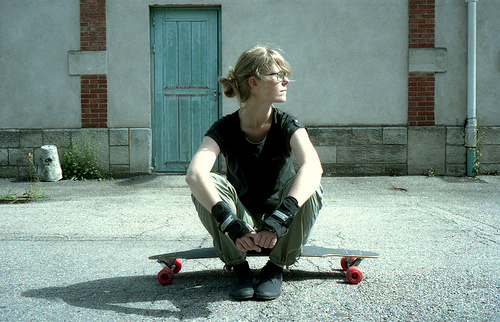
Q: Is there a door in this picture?
A: Yes, there is a door.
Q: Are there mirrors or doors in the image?
A: Yes, there is a door.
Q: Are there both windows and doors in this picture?
A: No, there is a door but no windows.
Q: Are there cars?
A: No, there are no cars.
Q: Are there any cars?
A: No, there are no cars.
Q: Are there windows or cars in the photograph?
A: No, there are no cars or windows.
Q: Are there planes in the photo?
A: No, there are no planes.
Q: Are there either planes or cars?
A: No, there are no planes or cars.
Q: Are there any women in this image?
A: Yes, there is a woman.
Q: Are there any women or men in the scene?
A: Yes, there is a woman.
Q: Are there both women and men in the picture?
A: No, there is a woman but no men.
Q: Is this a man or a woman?
A: This is a woman.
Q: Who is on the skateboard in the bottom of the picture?
A: The woman is on the skateboard.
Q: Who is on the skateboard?
A: The woman is on the skateboard.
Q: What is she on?
A: The woman is on the skateboard.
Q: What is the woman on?
A: The woman is on the skateboard.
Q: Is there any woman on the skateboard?
A: Yes, there is a woman on the skateboard.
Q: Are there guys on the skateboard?
A: No, there is a woman on the skateboard.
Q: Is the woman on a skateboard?
A: Yes, the woman is on a skateboard.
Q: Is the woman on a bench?
A: No, the woman is on a skateboard.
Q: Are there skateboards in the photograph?
A: Yes, there is a skateboard.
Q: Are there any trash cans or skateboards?
A: Yes, there is a skateboard.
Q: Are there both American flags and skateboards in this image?
A: No, there is a skateboard but no American flags.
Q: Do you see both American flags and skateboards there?
A: No, there is a skateboard but no American flags.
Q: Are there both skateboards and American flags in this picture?
A: No, there is a skateboard but no American flags.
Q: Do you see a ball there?
A: No, there are no balls.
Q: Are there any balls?
A: No, there are no balls.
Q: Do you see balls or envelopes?
A: No, there are no balls or envelopes.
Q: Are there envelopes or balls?
A: No, there are no balls or envelopes.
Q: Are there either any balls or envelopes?
A: No, there are no balls or envelopes.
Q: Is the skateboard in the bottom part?
A: Yes, the skateboard is in the bottom of the image.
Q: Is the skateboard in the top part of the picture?
A: No, the skateboard is in the bottom of the image.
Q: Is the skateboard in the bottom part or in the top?
A: The skateboard is in the bottom of the image.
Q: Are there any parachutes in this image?
A: No, there are no parachutes.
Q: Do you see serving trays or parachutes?
A: No, there are no parachutes or serving trays.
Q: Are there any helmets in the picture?
A: No, there are no helmets.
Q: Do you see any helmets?
A: No, there are no helmets.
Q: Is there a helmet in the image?
A: No, there are no helmets.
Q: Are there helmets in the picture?
A: No, there are no helmets.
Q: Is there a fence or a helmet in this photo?
A: No, there are no helmets or fences.